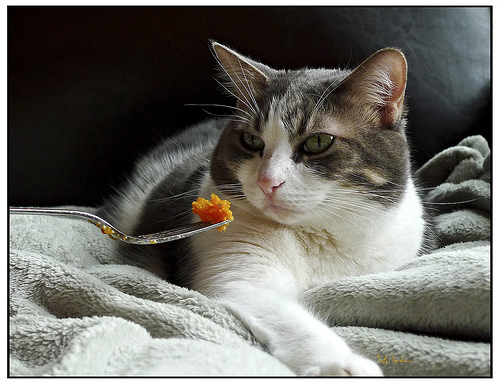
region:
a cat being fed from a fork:
[15, 12, 481, 367]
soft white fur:
[229, 246, 283, 306]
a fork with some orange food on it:
[187, 181, 248, 246]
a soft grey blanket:
[46, 245, 154, 354]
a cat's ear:
[320, 31, 442, 148]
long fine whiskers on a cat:
[354, 189, 499, 241]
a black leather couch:
[418, 17, 496, 105]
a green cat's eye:
[297, 112, 360, 167]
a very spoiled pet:
[22, 20, 468, 305]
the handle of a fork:
[21, 188, 130, 268]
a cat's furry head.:
[190, 43, 433, 213]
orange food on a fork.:
[181, 191, 249, 246]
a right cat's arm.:
[188, 291, 390, 383]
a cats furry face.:
[217, 111, 345, 231]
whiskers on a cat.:
[280, 49, 362, 147]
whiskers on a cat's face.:
[207, 60, 278, 134]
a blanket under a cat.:
[4, 130, 491, 377]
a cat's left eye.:
[286, 128, 338, 165]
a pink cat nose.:
[248, 163, 291, 209]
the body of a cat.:
[95, 106, 245, 280]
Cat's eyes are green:
[202, 96, 377, 184]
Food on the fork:
[49, 156, 261, 283]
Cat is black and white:
[88, 53, 482, 321]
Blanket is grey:
[32, 28, 464, 365]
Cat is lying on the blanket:
[52, 35, 463, 373]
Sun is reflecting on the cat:
[66, 27, 457, 374]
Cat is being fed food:
[72, 107, 496, 327]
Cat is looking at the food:
[149, 45, 419, 269]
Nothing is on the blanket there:
[389, 13, 483, 334]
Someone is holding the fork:
[16, 105, 303, 346]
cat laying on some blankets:
[41, 20, 451, 371]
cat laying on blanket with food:
[20, 35, 424, 289]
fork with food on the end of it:
[22, 164, 247, 285]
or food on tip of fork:
[189, 188, 239, 232]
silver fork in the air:
[1, 175, 183, 270]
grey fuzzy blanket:
[31, 270, 125, 382]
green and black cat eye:
[281, 121, 346, 161]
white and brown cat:
[192, 31, 420, 316]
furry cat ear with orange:
[311, 43, 418, 175]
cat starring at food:
[1, 35, 420, 325]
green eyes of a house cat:
[235, 125, 335, 155]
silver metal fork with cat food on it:
[10, 195, 240, 247]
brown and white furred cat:
[150, 30, 426, 370]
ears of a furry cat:
[205, 31, 410, 116]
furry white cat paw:
[231, 271, 392, 371]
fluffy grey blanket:
[10, 260, 200, 366]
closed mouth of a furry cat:
[250, 195, 305, 225]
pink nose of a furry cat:
[250, 165, 285, 190]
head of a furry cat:
[200, 35, 420, 210]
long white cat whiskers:
[310, 171, 480, 241]